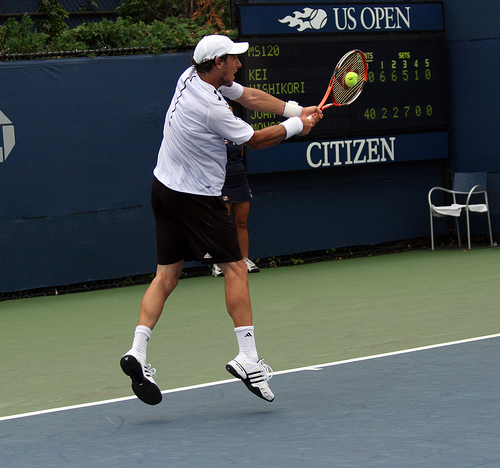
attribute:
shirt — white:
[146, 62, 250, 216]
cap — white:
[184, 26, 247, 78]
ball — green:
[340, 64, 364, 98]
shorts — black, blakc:
[141, 172, 253, 290]